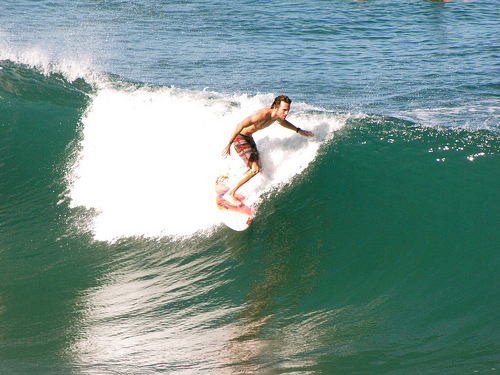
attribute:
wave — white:
[99, 103, 199, 217]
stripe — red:
[227, 131, 256, 170]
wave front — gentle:
[7, 215, 348, 372]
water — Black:
[3, 37, 483, 310]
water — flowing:
[24, 95, 476, 359]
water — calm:
[145, 32, 489, 113]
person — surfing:
[206, 87, 306, 224]